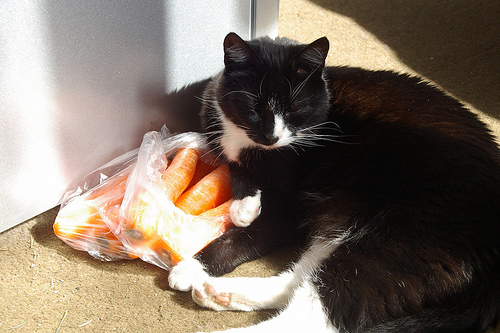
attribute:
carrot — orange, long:
[119, 136, 198, 245]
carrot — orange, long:
[54, 162, 133, 240]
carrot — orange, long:
[155, 196, 233, 265]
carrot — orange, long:
[128, 159, 231, 258]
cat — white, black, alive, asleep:
[166, 33, 497, 332]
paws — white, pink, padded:
[230, 198, 265, 227]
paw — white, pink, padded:
[169, 255, 207, 295]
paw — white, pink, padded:
[191, 277, 234, 310]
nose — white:
[264, 133, 278, 144]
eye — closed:
[240, 99, 259, 113]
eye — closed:
[284, 103, 306, 116]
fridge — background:
[1, 1, 279, 233]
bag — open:
[52, 124, 248, 273]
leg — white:
[191, 241, 338, 312]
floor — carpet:
[1, 1, 498, 332]